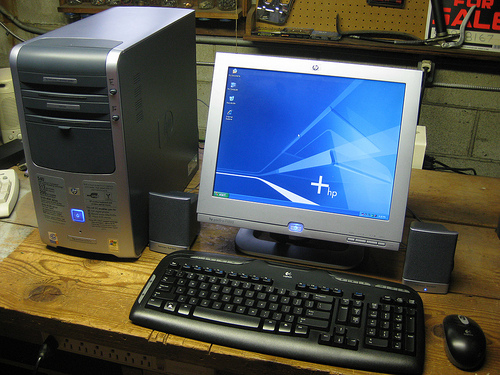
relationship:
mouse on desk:
[439, 309, 494, 375] [1, 148, 495, 369]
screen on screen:
[274, 102, 364, 176] [194, 49, 424, 254]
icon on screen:
[223, 111, 233, 122] [211, 66, 407, 215]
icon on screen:
[226, 95, 236, 108] [211, 66, 407, 215]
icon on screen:
[229, 68, 238, 78] [211, 66, 407, 215]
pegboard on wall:
[247, 2, 432, 49] [3, 1, 497, 75]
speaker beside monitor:
[393, 220, 470, 305] [181, 42, 436, 253]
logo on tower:
[67, 207, 87, 226] [3, 1, 203, 268]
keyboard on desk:
[125, 245, 427, 373] [1, 148, 495, 369]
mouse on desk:
[441, 312, 488, 369] [273, 204, 498, 371]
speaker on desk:
[393, 220, 470, 305] [1, 148, 495, 369]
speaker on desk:
[144, 184, 205, 254] [1, 148, 495, 369]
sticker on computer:
[47, 230, 58, 247] [14, 6, 201, 261]